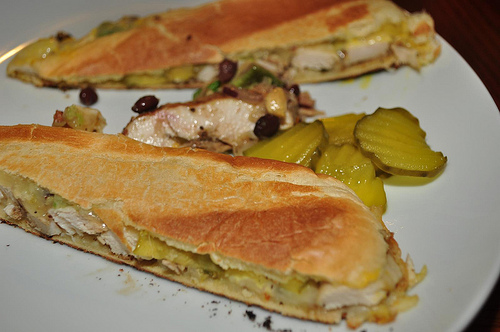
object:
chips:
[358, 110, 469, 173]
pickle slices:
[249, 115, 454, 164]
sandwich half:
[0, 119, 422, 329]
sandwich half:
[1, 0, 449, 87]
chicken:
[122, 89, 296, 154]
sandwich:
[6, 5, 442, 93]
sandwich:
[6, 116, 433, 328]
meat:
[119, 85, 261, 149]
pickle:
[309, 141, 386, 211]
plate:
[1, 0, 496, 329]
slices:
[358, 99, 448, 174]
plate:
[424, 171, 478, 301]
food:
[0, 174, 403, 279]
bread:
[5, 131, 387, 284]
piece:
[0, 121, 421, 324]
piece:
[7, 2, 438, 86]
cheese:
[337, 267, 383, 286]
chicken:
[48, 204, 109, 239]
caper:
[133, 96, 159, 115]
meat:
[43, 204, 104, 240]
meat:
[294, 39, 335, 73]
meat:
[340, 31, 389, 65]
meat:
[309, 270, 389, 315]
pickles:
[127, 66, 168, 91]